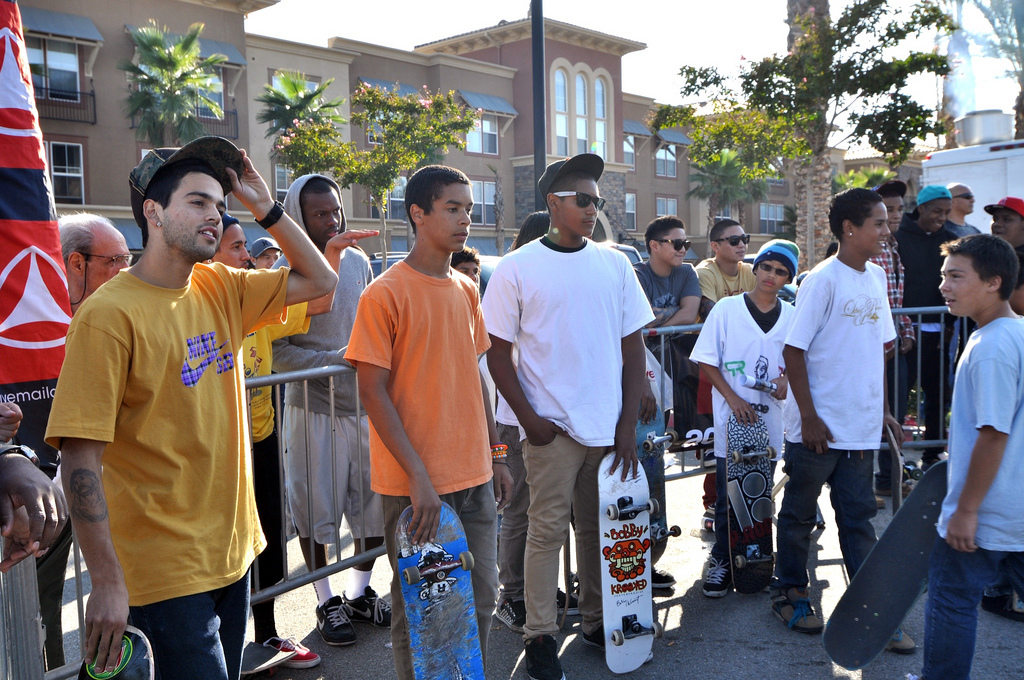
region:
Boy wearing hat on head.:
[120, 145, 286, 207]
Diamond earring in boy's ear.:
[152, 215, 168, 236]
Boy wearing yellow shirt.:
[72, 271, 279, 594]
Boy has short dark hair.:
[400, 152, 484, 222]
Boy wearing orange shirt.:
[359, 271, 511, 496]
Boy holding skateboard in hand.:
[397, 459, 475, 674]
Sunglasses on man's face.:
[562, 179, 611, 219]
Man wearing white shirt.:
[489, 224, 660, 459]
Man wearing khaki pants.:
[506, 427, 614, 677]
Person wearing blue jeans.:
[907, 516, 1013, 675]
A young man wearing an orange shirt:
[340, 151, 503, 506]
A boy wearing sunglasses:
[528, 146, 626, 249]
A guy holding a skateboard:
[499, 143, 684, 672]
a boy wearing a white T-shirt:
[784, 184, 925, 463]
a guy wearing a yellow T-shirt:
[43, 137, 342, 616]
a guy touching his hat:
[82, 130, 348, 336]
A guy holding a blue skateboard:
[341, 154, 509, 658]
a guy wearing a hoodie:
[283, 165, 369, 257]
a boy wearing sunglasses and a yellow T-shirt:
[698, 209, 760, 298]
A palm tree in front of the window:
[106, 10, 233, 138]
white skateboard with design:
[589, 440, 656, 671]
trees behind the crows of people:
[115, 18, 483, 193]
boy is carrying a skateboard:
[820, 228, 1017, 644]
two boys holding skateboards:
[393, 158, 697, 672]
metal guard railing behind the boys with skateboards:
[270, 361, 391, 578]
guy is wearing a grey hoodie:
[278, 165, 368, 397]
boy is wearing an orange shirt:
[331, 253, 532, 491]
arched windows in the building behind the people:
[551, 41, 632, 163]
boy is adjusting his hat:
[120, 124, 257, 205]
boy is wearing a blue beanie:
[732, 228, 796, 333]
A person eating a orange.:
[822, 203, 974, 505]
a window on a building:
[39, 40, 85, 107]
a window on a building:
[577, 59, 601, 159]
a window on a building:
[604, 54, 620, 159]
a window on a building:
[656, 129, 679, 177]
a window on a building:
[653, 183, 682, 232]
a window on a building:
[747, 193, 787, 226]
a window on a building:
[608, 192, 632, 218]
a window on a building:
[461, 119, 501, 164]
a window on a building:
[463, 174, 508, 226]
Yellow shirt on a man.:
[38, 237, 270, 614]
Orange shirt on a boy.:
[335, 268, 506, 503]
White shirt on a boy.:
[489, 224, 657, 456]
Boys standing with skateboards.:
[718, 221, 1022, 544]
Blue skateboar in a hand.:
[378, 497, 489, 676]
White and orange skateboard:
[581, 443, 659, 671]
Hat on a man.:
[114, 136, 239, 273]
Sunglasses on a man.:
[547, 181, 618, 220]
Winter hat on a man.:
[748, 230, 797, 285]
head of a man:
[131, 172, 227, 264]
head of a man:
[400, 160, 470, 252]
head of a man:
[542, 167, 599, 224]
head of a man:
[747, 246, 792, 292]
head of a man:
[827, 191, 889, 267]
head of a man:
[933, 235, 1011, 315]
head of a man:
[646, 217, 694, 262]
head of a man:
[705, 214, 745, 259]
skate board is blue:
[393, 499, 491, 676]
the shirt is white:
[476, 229, 651, 432]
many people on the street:
[69, 100, 980, 492]